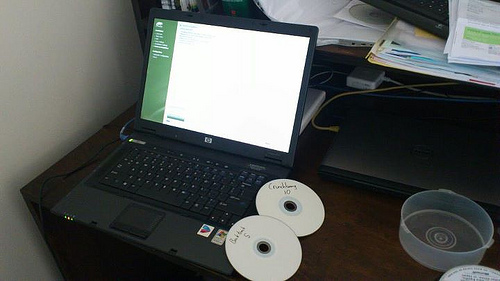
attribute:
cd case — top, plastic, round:
[407, 199, 462, 240]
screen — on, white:
[157, 25, 296, 146]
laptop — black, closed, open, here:
[67, 6, 302, 260]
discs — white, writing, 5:
[244, 206, 302, 248]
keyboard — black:
[107, 161, 208, 187]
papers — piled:
[369, 28, 428, 70]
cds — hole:
[254, 237, 278, 254]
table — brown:
[91, 128, 104, 134]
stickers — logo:
[195, 226, 226, 245]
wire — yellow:
[330, 93, 341, 96]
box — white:
[351, 73, 375, 85]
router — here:
[304, 103, 331, 113]